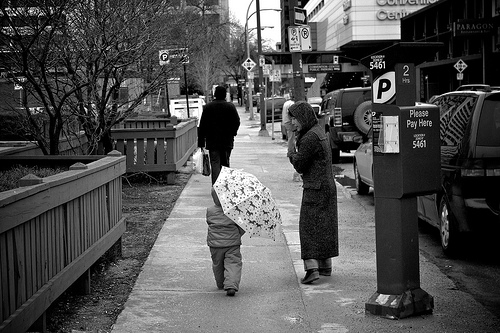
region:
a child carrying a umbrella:
[186, 164, 283, 287]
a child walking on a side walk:
[164, 159, 277, 318]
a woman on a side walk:
[280, 84, 329, 288]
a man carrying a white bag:
[191, 78, 238, 176]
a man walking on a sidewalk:
[188, 68, 241, 197]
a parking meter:
[359, 69, 440, 320]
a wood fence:
[12, 146, 130, 304]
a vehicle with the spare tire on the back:
[353, 74, 377, 143]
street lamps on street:
[241, 0, 284, 120]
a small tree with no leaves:
[54, 14, 169, 154]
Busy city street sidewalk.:
[188, 34, 347, 311]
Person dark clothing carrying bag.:
[194, 77, 253, 173]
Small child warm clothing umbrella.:
[206, 163, 285, 298]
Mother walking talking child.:
[263, 99, 337, 288]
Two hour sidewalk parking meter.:
[371, 66, 433, 317]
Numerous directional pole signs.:
[149, 28, 326, 104]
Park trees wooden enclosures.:
[5, 3, 136, 328]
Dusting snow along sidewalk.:
[131, 179, 208, 331]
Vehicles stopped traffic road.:
[324, 74, 496, 281]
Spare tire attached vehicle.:
[342, 87, 381, 137]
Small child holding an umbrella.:
[205, 163, 285, 298]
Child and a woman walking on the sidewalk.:
[205, 99, 343, 294]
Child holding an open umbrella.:
[202, 160, 283, 298]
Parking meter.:
[368, 32, 447, 319]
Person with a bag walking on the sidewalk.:
[195, 85, 241, 186]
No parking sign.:
[285, 25, 317, 53]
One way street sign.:
[292, 5, 309, 23]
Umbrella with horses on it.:
[213, 160, 281, 240]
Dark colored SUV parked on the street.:
[407, 83, 497, 254]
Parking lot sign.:
[154, 45, 191, 116]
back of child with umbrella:
[205, 165, 280, 295]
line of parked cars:
[265, 86, 499, 256]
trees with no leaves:
[15, 2, 233, 150]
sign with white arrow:
[292, 5, 310, 27]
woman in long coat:
[285, 100, 340, 282]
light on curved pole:
[242, 6, 281, 118]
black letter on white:
[370, 76, 393, 105]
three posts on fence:
[17, 148, 122, 187]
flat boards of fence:
[112, 135, 177, 168]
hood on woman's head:
[286, 100, 316, 134]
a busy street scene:
[15, 18, 457, 275]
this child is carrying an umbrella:
[205, 164, 269, 306]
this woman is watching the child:
[271, 87, 348, 286]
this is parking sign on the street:
[345, 61, 443, 319]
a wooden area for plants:
[8, 148, 156, 331]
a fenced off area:
[105, 101, 195, 174]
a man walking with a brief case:
[197, 81, 244, 175]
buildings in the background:
[232, 3, 470, 90]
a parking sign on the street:
[153, 43, 200, 73]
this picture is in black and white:
[22, 21, 467, 279]